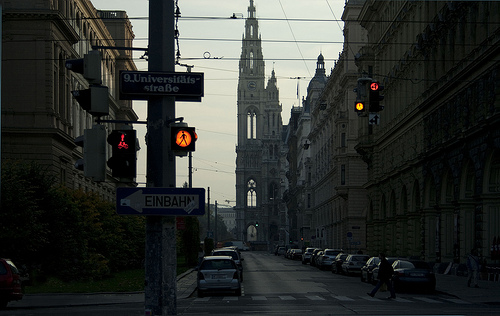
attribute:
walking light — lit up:
[165, 118, 202, 155]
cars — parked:
[276, 245, 416, 284]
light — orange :
[170, 118, 204, 154]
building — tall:
[234, 3, 289, 247]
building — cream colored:
[305, 3, 376, 258]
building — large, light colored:
[3, 3, 139, 213]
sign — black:
[115, 183, 205, 217]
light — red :
[331, 50, 391, 150]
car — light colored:
[199, 257, 242, 296]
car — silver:
[199, 252, 241, 288]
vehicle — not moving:
[195, 252, 241, 294]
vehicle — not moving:
[390, 255, 440, 291]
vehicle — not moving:
[342, 252, 373, 274]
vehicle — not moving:
[320, 247, 340, 266]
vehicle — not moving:
[303, 246, 313, 261]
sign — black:
[103, 64, 216, 108]